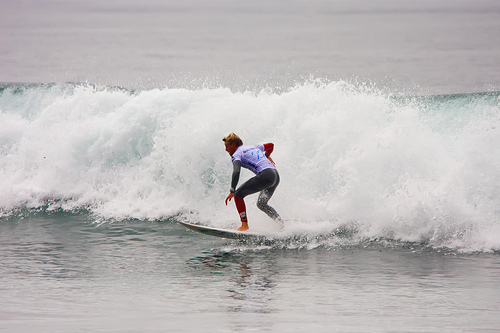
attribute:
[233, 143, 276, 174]
shirt — purple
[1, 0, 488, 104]
sky — blue 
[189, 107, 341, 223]
man — sufing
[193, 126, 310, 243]
man — sufing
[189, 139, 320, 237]
wetsuit — black and red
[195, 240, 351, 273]
waves — small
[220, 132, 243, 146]
hair — bright blonde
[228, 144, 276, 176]
t shirt — white 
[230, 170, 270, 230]
leg — long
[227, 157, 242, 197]
arm — long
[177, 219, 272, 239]
board — white 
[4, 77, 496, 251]
wave — big 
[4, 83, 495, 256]
foam — white 